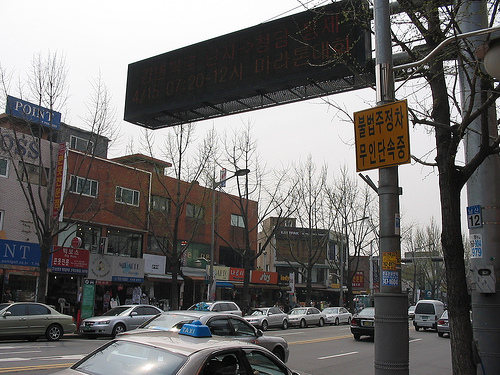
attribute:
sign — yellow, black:
[355, 108, 411, 161]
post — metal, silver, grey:
[372, 6, 404, 313]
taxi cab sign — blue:
[174, 324, 211, 338]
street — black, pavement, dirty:
[1, 324, 457, 374]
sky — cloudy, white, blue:
[3, 5, 480, 225]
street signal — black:
[128, 5, 378, 117]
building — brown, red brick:
[55, 149, 259, 307]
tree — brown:
[269, 170, 334, 303]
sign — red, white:
[56, 246, 87, 266]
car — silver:
[244, 307, 293, 327]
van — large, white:
[413, 298, 441, 331]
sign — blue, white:
[6, 99, 63, 127]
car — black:
[352, 304, 385, 336]